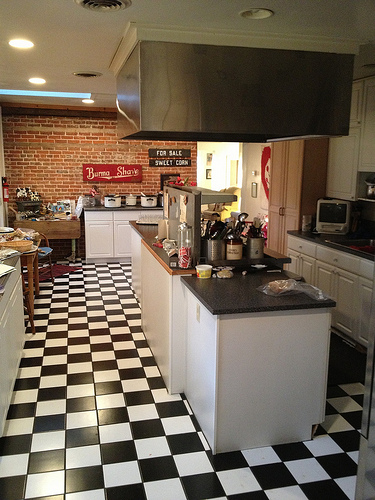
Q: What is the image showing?
A: It is showing a kitchen.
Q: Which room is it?
A: It is a kitchen.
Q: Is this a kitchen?
A: Yes, it is a kitchen.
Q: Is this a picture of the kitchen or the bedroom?
A: It is showing the kitchen.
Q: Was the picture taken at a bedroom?
A: No, the picture was taken in a kitchen.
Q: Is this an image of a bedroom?
A: No, the picture is showing a kitchen.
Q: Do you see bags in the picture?
A: Yes, there is a bag.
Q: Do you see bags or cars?
A: Yes, there is a bag.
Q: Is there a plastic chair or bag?
A: Yes, there is a plastic bag.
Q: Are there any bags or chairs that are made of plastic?
A: Yes, the bag is made of plastic.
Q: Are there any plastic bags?
A: Yes, there is a bag that is made of plastic.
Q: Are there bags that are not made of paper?
A: Yes, there is a bag that is made of plastic.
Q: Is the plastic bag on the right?
A: Yes, the bag is on the right of the image.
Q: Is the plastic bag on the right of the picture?
A: Yes, the bag is on the right of the image.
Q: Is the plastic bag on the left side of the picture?
A: No, the bag is on the right of the image.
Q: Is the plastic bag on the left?
A: No, the bag is on the right of the image.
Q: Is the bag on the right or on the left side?
A: The bag is on the right of the image.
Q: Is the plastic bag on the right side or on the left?
A: The bag is on the right of the image.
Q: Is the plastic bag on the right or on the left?
A: The bag is on the right of the image.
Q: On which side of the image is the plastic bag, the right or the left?
A: The bag is on the right of the image.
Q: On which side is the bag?
A: The bag is on the right of the image.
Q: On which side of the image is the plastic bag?
A: The bag is on the right of the image.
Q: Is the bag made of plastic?
A: Yes, the bag is made of plastic.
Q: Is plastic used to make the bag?
A: Yes, the bag is made of plastic.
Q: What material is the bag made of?
A: The bag is made of plastic.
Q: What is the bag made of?
A: The bag is made of plastic.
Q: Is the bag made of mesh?
A: No, the bag is made of plastic.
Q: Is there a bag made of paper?
A: No, there is a bag but it is made of plastic.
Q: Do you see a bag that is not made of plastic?
A: No, there is a bag but it is made of plastic.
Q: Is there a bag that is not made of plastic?
A: No, there is a bag but it is made of plastic.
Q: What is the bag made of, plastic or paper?
A: The bag is made of plastic.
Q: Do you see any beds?
A: No, there are no beds.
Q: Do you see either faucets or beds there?
A: No, there are no beds or faucets.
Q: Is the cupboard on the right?
A: Yes, the cupboard is on the right of the image.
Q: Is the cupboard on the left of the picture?
A: No, the cupboard is on the right of the image.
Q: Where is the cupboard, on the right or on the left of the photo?
A: The cupboard is on the right of the image.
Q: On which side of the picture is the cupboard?
A: The cupboard is on the right of the image.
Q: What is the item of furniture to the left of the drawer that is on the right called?
A: The piece of furniture is a cupboard.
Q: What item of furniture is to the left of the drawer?
A: The piece of furniture is a cupboard.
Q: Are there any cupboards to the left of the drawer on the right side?
A: Yes, there is a cupboard to the left of the drawer.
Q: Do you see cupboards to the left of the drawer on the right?
A: Yes, there is a cupboard to the left of the drawer.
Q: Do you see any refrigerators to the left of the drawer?
A: No, there is a cupboard to the left of the drawer.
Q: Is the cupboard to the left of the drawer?
A: Yes, the cupboard is to the left of the drawer.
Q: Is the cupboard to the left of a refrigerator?
A: No, the cupboard is to the left of the drawer.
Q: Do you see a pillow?
A: No, there are no pillows.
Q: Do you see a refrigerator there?
A: No, there are no refrigerators.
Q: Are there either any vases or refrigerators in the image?
A: No, there are no refrigerators or vases.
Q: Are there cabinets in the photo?
A: Yes, there is a cabinet.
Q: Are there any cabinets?
A: Yes, there is a cabinet.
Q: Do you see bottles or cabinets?
A: Yes, there is a cabinet.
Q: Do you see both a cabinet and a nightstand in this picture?
A: No, there is a cabinet but no nightstands.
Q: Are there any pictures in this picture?
A: No, there are no pictures.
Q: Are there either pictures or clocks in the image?
A: No, there are no pictures or clocks.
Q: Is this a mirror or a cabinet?
A: This is a cabinet.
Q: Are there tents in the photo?
A: No, there are no tents.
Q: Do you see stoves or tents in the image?
A: No, there are no tents or stoves.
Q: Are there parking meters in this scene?
A: No, there are no parking meters.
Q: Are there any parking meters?
A: No, there are no parking meters.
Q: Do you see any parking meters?
A: No, there are no parking meters.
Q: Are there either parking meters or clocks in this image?
A: No, there are no parking meters or clocks.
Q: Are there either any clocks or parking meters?
A: No, there are no parking meters or clocks.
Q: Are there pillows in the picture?
A: No, there are no pillows.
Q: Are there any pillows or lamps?
A: No, there are no pillows or lamps.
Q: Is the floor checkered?
A: Yes, the floor is checkered.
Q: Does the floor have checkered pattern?
A: Yes, the floor is checkered.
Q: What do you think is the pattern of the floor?
A: The floor is checkered.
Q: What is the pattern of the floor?
A: The floor is checkered.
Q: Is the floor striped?
A: No, the floor is checkered.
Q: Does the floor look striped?
A: No, the floor is checkered.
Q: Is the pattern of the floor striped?
A: No, the floor is checkered.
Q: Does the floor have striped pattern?
A: No, the floor is checkered.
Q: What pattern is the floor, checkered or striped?
A: The floor is checkered.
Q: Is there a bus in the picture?
A: No, there are no buses.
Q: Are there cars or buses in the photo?
A: No, there are no buses or cars.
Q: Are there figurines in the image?
A: No, there are no figurines.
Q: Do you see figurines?
A: No, there are no figurines.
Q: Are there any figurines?
A: No, there are no figurines.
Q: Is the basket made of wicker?
A: Yes, the basket is made of wicker.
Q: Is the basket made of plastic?
A: No, the basket is made of wicker.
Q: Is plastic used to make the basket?
A: No, the basket is made of wicker.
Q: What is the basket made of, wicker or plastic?
A: The basket is made of wicker.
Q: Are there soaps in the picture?
A: No, there are no soaps.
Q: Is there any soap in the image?
A: No, there are no soaps.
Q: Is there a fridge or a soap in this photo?
A: No, there are no soaps or refrigerators.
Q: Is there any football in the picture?
A: No, there are no footballs.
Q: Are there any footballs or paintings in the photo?
A: No, there are no footballs or paintings.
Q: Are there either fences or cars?
A: No, there are no cars or fences.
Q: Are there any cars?
A: No, there are no cars.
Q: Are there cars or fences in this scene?
A: No, there are no cars or fences.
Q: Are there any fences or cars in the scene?
A: No, there are no cars or fences.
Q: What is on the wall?
A: The sign is on the wall.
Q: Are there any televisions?
A: Yes, there is a television.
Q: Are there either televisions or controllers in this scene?
A: Yes, there is a television.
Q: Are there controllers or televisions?
A: Yes, there is a television.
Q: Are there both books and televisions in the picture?
A: No, there is a television but no books.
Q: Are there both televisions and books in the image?
A: No, there is a television but no books.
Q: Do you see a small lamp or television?
A: Yes, there is a small television.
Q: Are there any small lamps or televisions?
A: Yes, there is a small television.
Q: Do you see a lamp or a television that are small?
A: Yes, the television is small.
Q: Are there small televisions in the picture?
A: Yes, there is a small television.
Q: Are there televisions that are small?
A: Yes, there is a television that is small.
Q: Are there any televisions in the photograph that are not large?
A: Yes, there is a small television.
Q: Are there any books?
A: No, there are no books.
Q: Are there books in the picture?
A: No, there are no books.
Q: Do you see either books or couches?
A: No, there are no books or couches.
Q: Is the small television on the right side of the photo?
A: Yes, the television is on the right of the image.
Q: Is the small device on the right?
A: Yes, the television is on the right of the image.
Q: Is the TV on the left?
A: No, the TV is on the right of the image.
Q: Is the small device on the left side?
A: No, the TV is on the right of the image.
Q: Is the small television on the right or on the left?
A: The TV is on the right of the image.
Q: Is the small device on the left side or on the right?
A: The TV is on the right of the image.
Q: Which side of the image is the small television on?
A: The TV is on the right of the image.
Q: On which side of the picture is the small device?
A: The TV is on the right of the image.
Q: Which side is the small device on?
A: The TV is on the right of the image.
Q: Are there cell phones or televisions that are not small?
A: No, there is a television but it is small.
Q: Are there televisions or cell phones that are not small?
A: No, there is a television but it is small.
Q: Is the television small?
A: Yes, the television is small.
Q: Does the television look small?
A: Yes, the television is small.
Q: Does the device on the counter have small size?
A: Yes, the television is small.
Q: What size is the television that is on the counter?
A: The TV is small.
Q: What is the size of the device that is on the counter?
A: The TV is small.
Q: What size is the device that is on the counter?
A: The TV is small.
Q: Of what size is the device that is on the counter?
A: The TV is small.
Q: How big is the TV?
A: The TV is small.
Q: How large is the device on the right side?
A: The TV is small.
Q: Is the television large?
A: No, the television is small.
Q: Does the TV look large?
A: No, the TV is small.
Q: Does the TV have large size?
A: No, the TV is small.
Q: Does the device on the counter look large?
A: No, the TV is small.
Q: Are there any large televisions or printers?
A: No, there is a television but it is small.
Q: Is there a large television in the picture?
A: No, there is a television but it is small.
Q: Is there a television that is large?
A: No, there is a television but it is small.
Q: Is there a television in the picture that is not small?
A: No, there is a television but it is small.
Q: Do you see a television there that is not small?
A: No, there is a television but it is small.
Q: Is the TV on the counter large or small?
A: The TV is small.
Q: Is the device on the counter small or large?
A: The TV is small.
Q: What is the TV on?
A: The TV is on the counter.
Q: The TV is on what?
A: The TV is on the counter.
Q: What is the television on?
A: The TV is on the counter.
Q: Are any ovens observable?
A: No, there are no ovens.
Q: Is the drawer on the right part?
A: Yes, the drawer is on the right of the image.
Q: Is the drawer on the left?
A: No, the drawer is on the right of the image.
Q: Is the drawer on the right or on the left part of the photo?
A: The drawer is on the right of the image.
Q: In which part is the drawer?
A: The drawer is on the right of the image.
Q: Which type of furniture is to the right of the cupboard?
A: The piece of furniture is a drawer.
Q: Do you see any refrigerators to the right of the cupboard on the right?
A: No, there is a drawer to the right of the cupboard.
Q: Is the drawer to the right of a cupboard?
A: Yes, the drawer is to the right of a cupboard.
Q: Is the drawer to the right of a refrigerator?
A: No, the drawer is to the right of a cupboard.